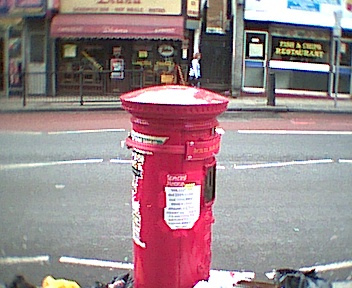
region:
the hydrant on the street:
[99, 81, 241, 286]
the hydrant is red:
[110, 81, 228, 286]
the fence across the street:
[5, 62, 144, 105]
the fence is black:
[12, 64, 170, 95]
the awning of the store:
[44, 16, 193, 34]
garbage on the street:
[13, 275, 120, 285]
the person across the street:
[183, 48, 210, 91]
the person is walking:
[182, 48, 214, 88]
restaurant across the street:
[245, 25, 350, 78]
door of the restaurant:
[242, 26, 268, 96]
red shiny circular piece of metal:
[117, 82, 232, 111]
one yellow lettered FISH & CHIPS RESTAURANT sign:
[271, 35, 327, 59]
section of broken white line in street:
[216, 155, 349, 169]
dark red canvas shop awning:
[48, 12, 185, 41]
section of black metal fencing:
[1, 63, 124, 104]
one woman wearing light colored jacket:
[189, 49, 202, 78]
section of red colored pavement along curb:
[236, 98, 350, 137]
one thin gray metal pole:
[333, 38, 343, 110]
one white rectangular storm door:
[23, 29, 50, 96]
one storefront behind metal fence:
[53, 1, 186, 103]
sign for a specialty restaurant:
[273, 39, 326, 57]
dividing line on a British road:
[234, 153, 332, 171]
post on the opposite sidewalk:
[266, 73, 275, 105]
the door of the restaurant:
[241, 29, 268, 92]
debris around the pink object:
[201, 266, 329, 286]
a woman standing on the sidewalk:
[187, 51, 202, 85]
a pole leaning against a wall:
[175, 65, 186, 85]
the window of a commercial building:
[80, 42, 108, 84]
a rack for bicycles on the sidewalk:
[21, 69, 146, 104]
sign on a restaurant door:
[249, 43, 263, 57]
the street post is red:
[119, 82, 228, 287]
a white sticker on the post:
[161, 184, 200, 229]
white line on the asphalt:
[59, 254, 136, 277]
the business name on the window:
[272, 40, 327, 59]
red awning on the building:
[49, 14, 183, 39]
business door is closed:
[240, 29, 268, 94]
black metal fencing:
[0, 66, 144, 105]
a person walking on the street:
[188, 52, 202, 83]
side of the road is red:
[1, 111, 350, 131]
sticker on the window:
[137, 49, 146, 58]